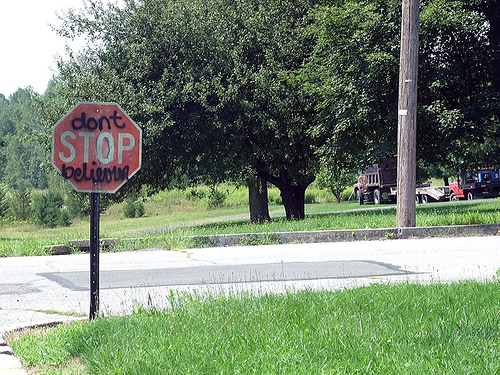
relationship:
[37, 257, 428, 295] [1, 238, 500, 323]
patch in road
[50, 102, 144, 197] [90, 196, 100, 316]
sign on a pole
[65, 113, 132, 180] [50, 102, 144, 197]
graffiti on sign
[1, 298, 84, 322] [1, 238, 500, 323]
crack in road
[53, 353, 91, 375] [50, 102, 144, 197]
dirt by sign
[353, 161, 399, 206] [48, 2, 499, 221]
truck behind tree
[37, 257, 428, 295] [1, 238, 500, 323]
patch on road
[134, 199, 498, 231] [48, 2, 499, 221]
road other side of tree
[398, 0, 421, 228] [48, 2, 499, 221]
pole by tree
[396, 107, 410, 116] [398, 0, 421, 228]
white sticker on pole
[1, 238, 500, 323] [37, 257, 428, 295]
road with a patch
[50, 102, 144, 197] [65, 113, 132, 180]
sign with graffiti